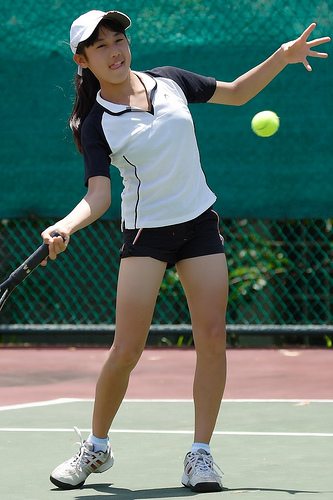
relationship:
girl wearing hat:
[40, 9, 331, 488] [69, 10, 131, 50]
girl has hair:
[40, 9, 331, 488] [66, 19, 130, 153]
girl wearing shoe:
[40, 9, 331, 488] [50, 446, 115, 492]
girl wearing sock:
[40, 9, 331, 488] [89, 432, 110, 450]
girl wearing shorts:
[40, 9, 331, 488] [119, 211, 226, 261]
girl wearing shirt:
[40, 9, 331, 488] [76, 62, 217, 229]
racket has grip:
[0, 229, 67, 322] [12, 228, 62, 284]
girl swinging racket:
[40, 9, 331, 488] [0, 229, 67, 322]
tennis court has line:
[2, 343, 330, 499] [2, 391, 331, 412]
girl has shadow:
[40, 9, 331, 488] [57, 475, 321, 500]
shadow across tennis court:
[57, 475, 321, 500] [2, 343, 330, 499]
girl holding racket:
[40, 9, 331, 488] [0, 229, 67, 322]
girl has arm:
[40, 9, 331, 488] [150, 49, 288, 112]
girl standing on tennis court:
[40, 9, 331, 488] [2, 343, 330, 499]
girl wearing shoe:
[40, 9, 331, 488] [180, 450, 220, 491]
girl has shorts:
[40, 9, 331, 488] [119, 211, 226, 261]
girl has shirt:
[40, 9, 331, 488] [76, 62, 217, 229]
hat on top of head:
[69, 10, 131, 50] [70, 11, 134, 84]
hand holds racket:
[39, 227, 74, 263] [0, 229, 67, 322]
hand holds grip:
[39, 227, 74, 263] [12, 228, 62, 284]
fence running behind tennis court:
[2, 2, 332, 346] [2, 343, 330, 499]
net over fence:
[0, 4, 332, 224] [2, 2, 332, 346]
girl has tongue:
[40, 9, 331, 488] [110, 62, 123, 71]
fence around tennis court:
[2, 2, 332, 346] [2, 343, 330, 499]